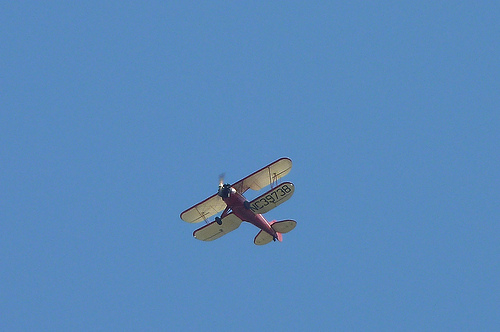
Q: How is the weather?
A: It is clear.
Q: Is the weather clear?
A: Yes, it is clear.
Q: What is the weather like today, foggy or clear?
A: It is clear.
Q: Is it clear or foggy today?
A: It is clear.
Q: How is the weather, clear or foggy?
A: It is clear.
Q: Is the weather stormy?
A: No, it is clear.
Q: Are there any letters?
A: Yes, there are letters.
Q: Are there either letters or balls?
A: Yes, there are letters.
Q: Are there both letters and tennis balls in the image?
A: No, there are letters but no tennis balls.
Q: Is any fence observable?
A: No, there are no fences.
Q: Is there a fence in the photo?
A: No, there are no fences.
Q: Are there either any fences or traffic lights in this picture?
A: No, there are no fences or traffic lights.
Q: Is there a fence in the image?
A: No, there are no fences.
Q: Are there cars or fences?
A: No, there are no fences or cars.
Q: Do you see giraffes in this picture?
A: No, there are no giraffes.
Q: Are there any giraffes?
A: No, there are no giraffes.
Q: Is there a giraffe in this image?
A: No, there are no giraffes.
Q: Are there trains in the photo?
A: No, there are no trains.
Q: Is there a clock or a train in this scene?
A: No, there are no trains or clocks.